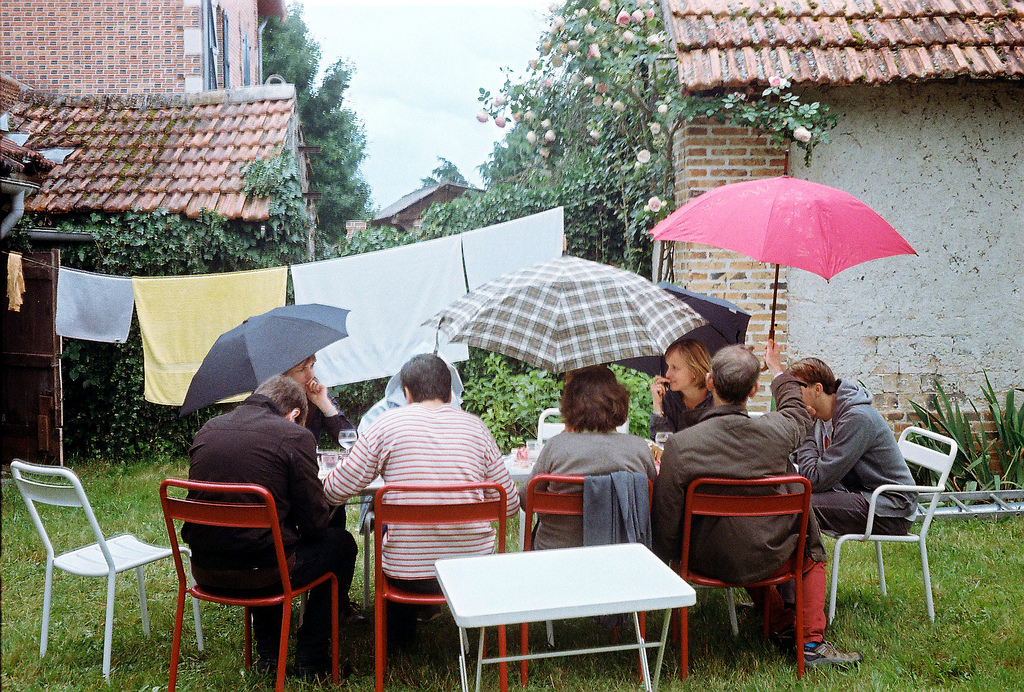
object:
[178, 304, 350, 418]
umbrella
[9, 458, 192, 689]
chair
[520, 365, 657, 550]
lady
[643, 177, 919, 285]
umbrella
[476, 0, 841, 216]
roses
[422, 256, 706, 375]
umbrella